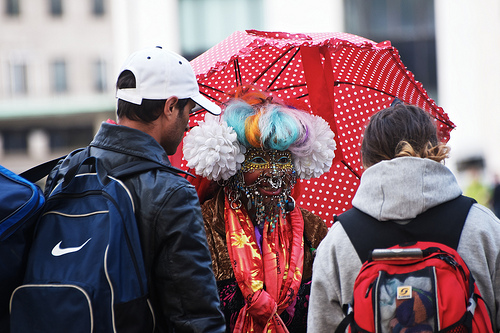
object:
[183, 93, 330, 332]
woman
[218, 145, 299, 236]
facial piercings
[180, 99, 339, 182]
wig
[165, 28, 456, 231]
umbrella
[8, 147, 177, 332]
backpack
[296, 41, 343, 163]
red ribbon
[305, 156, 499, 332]
hoodie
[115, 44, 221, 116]
cap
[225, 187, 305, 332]
scarf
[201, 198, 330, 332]
jacket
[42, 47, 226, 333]
man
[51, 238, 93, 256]
nike sign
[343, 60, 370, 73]
polka dots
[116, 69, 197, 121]
brown hair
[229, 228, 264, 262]
yellow leaf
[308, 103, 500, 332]
woman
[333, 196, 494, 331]
bag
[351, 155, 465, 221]
hood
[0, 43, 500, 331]
three people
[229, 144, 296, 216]
face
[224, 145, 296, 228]
mask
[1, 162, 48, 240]
duffle bag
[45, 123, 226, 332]
jacket